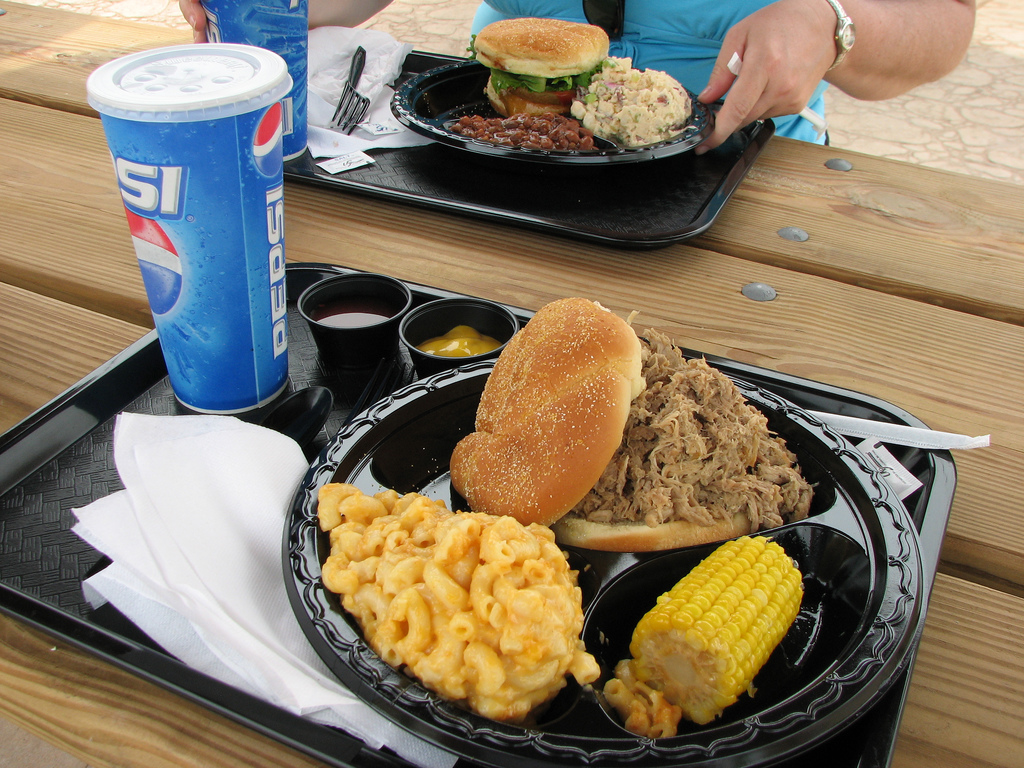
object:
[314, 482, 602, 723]
macaroni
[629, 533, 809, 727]
corn